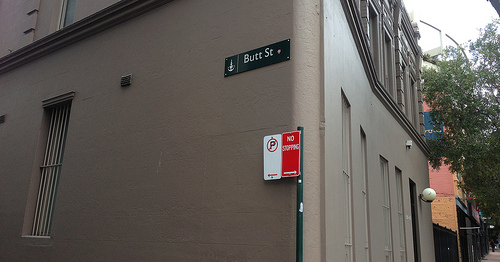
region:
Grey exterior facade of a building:
[85, 150, 244, 217]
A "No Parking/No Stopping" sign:
[262, 116, 303, 259]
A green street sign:
[224, 37, 299, 77]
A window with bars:
[18, 98, 73, 240]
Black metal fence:
[433, 221, 461, 260]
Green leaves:
[438, 70, 498, 111]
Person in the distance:
[486, 238, 499, 252]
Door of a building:
[407, 174, 421, 260]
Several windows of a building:
[362, 1, 420, 92]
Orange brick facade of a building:
[434, 198, 455, 223]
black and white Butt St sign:
[225, 39, 294, 70]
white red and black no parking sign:
[261, 132, 283, 178]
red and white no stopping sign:
[282, 131, 299, 177]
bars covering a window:
[21, 98, 70, 240]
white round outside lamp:
[416, 183, 441, 205]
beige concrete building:
[310, 11, 380, 260]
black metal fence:
[436, 217, 460, 260]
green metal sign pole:
[295, 176, 305, 260]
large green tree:
[426, 22, 498, 259]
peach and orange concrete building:
[433, 167, 459, 227]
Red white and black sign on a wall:
[251, 115, 314, 187]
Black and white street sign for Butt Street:
[217, 37, 292, 74]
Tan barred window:
[25, 88, 80, 260]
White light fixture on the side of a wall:
[419, 184, 436, 203]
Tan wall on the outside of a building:
[118, 108, 238, 208]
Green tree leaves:
[429, 62, 496, 184]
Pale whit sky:
[425, 2, 481, 26]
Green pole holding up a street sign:
[258, 120, 310, 256]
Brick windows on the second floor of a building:
[363, 8, 425, 119]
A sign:
[213, 78, 334, 240]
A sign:
[260, 126, 349, 249]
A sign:
[246, 104, 315, 249]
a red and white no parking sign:
[245, 108, 327, 225]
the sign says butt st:
[211, 26, 310, 84]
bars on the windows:
[18, 76, 79, 250]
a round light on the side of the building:
[409, 173, 449, 223]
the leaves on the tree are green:
[417, 19, 497, 224]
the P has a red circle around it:
[253, 124, 300, 165]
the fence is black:
[421, 210, 470, 260]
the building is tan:
[0, 0, 432, 261]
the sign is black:
[205, 28, 309, 83]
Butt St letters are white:
[229, 35, 292, 79]